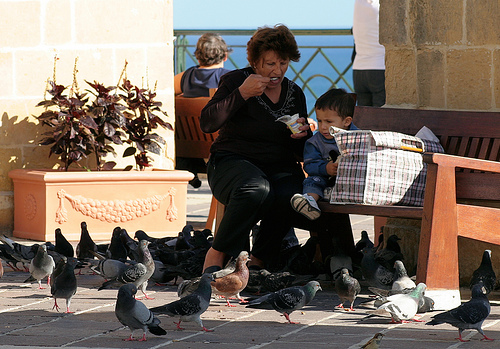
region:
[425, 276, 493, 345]
This is a dove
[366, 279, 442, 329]
This is a dove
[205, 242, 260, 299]
This is a dove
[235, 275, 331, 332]
This is a dove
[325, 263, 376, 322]
This is a dove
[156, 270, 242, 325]
This is a dove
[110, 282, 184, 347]
This is a dove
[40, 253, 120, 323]
This is a dove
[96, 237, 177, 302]
This is a dove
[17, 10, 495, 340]
woman sitting on bench surrounded by pigeons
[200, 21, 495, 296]
woman and little boy sitting on bench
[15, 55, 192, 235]
plants in a planter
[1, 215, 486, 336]
lots of pigeons on the ground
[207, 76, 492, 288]
wooden bench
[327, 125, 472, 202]
large picnic bag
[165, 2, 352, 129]
blue sky and ocean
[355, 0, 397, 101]
woman standing by the railing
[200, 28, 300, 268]
woman eating something out of a container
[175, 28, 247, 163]
man sitting on bench across from water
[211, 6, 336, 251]
this woman is eating yogurt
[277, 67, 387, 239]
this is a little boy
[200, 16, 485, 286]
they are sitting down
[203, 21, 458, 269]
they are on a bench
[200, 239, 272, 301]
this pigeon is brown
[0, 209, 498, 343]
they are surrounded by a flock of pigeons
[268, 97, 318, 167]
a white cup of yogurt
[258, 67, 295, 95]
the spoon is in her mouth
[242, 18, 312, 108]
her mouth is eating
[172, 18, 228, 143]
this guy is sitting on a bench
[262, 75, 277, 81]
spoon in woman's mouth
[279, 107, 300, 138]
cup in woman's hand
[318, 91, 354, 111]
the little boy's black hair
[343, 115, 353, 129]
the boy's left ear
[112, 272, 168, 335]
pigeon on the ground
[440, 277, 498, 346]
black pigeon walking on ground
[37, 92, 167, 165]
purple plants on stand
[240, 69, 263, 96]
the woman's right hand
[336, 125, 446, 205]
bag sitting on bench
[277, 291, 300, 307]
the bird' s right wing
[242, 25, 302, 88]
head of a person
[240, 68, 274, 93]
hand of a person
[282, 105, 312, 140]
hand of a person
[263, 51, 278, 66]
eye of a person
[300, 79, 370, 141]
head of a person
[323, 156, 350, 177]
hand of a person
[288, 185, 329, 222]
feet of a person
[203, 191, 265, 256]
leg of a person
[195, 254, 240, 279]
feet of a person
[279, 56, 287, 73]
eye of a person